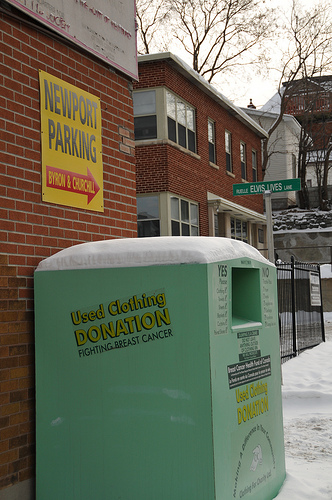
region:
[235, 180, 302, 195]
green street sign on corner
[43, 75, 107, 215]
yellow parking sign on building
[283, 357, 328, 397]
white snow on the ground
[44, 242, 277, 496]
used clothes donation bin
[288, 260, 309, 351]
black security gate around building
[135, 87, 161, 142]
window on the brick building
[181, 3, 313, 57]
trees with no leaves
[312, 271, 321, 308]
sign attached to black security gate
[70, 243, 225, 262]
white snow on top of bin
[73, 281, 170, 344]
used clothing donation written in yellow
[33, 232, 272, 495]
a donation center is next to the building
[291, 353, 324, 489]
the area is coverd in snow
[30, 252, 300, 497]
the donation bin is green in color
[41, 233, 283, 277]
the top of the donation bin is covered in snow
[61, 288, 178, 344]
the donation center is for clothing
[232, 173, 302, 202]
a street sign is displayed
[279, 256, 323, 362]
a black fence can be seen in the background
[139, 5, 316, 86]
the trees do not have any leaves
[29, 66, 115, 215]
a yellow sign hangs on the building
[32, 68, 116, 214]
they yellow sign is for Newport Parking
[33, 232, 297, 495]
a used clothing donation box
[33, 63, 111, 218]
yellow sign with black writing and a red arrow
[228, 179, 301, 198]
a green and white street sign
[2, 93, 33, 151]
the bricks of a wall of a building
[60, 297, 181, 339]
yellow letters on the side of a donation box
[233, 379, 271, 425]
yellow letters on the side of a donation box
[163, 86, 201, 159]
the windows of a building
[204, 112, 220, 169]
a window of a building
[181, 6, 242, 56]
the branches of a tree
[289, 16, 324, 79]
the branches of a tree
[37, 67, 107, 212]
A sign giving directions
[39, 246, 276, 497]
A clothing donation box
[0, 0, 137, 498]
The corner of a brick building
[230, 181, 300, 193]
A green street sign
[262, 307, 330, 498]
Snow on the ground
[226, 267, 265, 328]
The opening of the box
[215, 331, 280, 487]
Words on the front of the box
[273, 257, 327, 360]
A black metal fence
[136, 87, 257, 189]
Windows on a brick building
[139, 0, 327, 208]
Trees behind the building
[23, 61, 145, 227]
A yellow sign is on the building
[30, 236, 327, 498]
A donation box is on the street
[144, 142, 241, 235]
The building is made of red brick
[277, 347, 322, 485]
The ground is covered in snow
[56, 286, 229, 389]
Writing is on the bin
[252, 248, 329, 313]
A black fence is next to the building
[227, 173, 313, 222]
A green street sign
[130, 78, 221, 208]
Windows are on the building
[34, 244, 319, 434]
The bin is green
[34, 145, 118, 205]
A sign has a red arrow